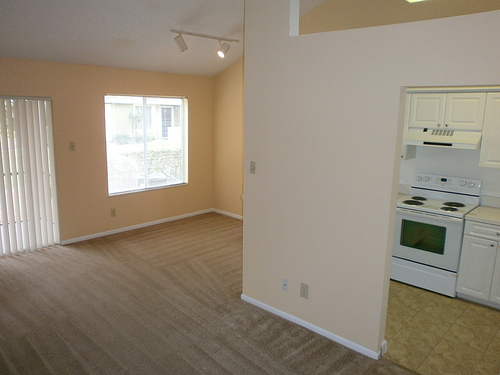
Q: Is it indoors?
A: Yes, it is indoors.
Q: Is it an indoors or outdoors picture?
A: It is indoors.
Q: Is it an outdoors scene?
A: No, it is indoors.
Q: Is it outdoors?
A: No, it is indoors.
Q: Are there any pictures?
A: No, there are no pictures.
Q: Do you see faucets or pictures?
A: No, there are no pictures or faucets.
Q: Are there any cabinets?
A: Yes, there is a cabinet.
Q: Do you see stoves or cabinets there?
A: Yes, there is a cabinet.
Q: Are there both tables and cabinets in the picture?
A: No, there is a cabinet but no tables.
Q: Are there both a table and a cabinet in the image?
A: No, there is a cabinet but no tables.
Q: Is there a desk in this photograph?
A: No, there are no desks.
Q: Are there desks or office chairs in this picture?
A: No, there are no desks or office chairs.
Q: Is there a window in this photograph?
A: Yes, there is a window.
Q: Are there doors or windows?
A: Yes, there is a window.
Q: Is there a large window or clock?
A: Yes, there is a large window.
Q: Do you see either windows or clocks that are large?
A: Yes, the window is large.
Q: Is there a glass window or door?
A: Yes, there is a glass window.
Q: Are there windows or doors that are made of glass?
A: Yes, the window is made of glass.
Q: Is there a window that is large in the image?
A: Yes, there is a large window.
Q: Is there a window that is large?
A: Yes, there is a window that is large.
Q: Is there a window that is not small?
A: Yes, there is a large window.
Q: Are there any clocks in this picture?
A: No, there are no clocks.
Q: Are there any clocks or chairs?
A: No, there are no clocks or chairs.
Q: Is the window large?
A: Yes, the window is large.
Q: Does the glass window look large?
A: Yes, the window is large.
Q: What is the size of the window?
A: The window is large.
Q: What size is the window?
A: The window is large.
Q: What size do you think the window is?
A: The window is large.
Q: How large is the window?
A: The window is large.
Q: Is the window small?
A: No, the window is large.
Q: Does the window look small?
A: No, the window is large.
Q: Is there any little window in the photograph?
A: No, there is a window but it is large.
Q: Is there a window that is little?
A: No, there is a window but it is large.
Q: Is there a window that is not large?
A: No, there is a window but it is large.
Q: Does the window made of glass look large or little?
A: The window is large.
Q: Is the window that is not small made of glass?
A: Yes, the window is made of glass.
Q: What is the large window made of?
A: The window is made of glass.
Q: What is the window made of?
A: The window is made of glass.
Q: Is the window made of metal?
A: No, the window is made of glass.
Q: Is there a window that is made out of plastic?
A: No, there is a window but it is made of glass.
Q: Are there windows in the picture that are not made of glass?
A: No, there is a window but it is made of glass.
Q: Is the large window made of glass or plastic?
A: The window is made of glass.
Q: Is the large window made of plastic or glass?
A: The window is made of glass.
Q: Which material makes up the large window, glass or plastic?
A: The window is made of glass.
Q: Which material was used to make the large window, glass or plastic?
A: The window is made of glass.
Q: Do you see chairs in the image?
A: No, there are no chairs.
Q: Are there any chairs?
A: No, there are no chairs.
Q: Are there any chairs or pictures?
A: No, there are no chairs or pictures.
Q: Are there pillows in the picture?
A: No, there are no pillows.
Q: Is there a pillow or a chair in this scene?
A: No, there are no pillows or chairs.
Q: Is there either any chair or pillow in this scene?
A: No, there are no pillows or chairs.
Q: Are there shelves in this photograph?
A: No, there are no shelves.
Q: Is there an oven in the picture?
A: Yes, there is an oven.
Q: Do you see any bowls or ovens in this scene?
A: Yes, there is an oven.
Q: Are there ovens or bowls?
A: Yes, there is an oven.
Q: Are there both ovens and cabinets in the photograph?
A: Yes, there are both an oven and a cabinet.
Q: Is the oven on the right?
A: Yes, the oven is on the right of the image.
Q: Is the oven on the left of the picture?
A: No, the oven is on the right of the image.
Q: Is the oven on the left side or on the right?
A: The oven is on the right of the image.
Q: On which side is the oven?
A: The oven is on the right of the image.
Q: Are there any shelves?
A: No, there are no shelves.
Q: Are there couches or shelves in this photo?
A: No, there are no shelves or couches.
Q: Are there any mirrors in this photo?
A: No, there are no mirrors.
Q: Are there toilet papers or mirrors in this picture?
A: No, there are no mirrors or toilet papers.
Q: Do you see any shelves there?
A: No, there are no shelves.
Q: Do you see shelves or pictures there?
A: No, there are no shelves or pictures.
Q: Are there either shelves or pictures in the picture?
A: No, there are no shelves or pictures.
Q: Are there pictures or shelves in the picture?
A: No, there are no shelves or pictures.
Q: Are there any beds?
A: No, there are no beds.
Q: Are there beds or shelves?
A: No, there are no beds or shelves.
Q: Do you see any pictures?
A: No, there are no pictures.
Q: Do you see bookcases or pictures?
A: No, there are no pictures or bookcases.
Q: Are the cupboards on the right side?
A: Yes, the cupboards are on the right of the image.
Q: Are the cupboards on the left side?
A: No, the cupboards are on the right of the image.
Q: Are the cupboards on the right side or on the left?
A: The cupboards are on the right of the image.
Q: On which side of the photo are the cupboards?
A: The cupboards are on the right of the image.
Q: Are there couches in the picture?
A: No, there are no couches.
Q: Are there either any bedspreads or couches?
A: No, there are no couches or bedspreads.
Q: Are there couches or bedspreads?
A: No, there are no couches or bedspreads.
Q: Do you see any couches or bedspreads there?
A: No, there are no couches or bedspreads.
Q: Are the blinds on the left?
A: Yes, the blinds are on the left of the image.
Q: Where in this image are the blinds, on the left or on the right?
A: The blinds are on the left of the image.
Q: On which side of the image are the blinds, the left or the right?
A: The blinds are on the left of the image.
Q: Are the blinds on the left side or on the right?
A: The blinds are on the left of the image.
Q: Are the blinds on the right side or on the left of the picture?
A: The blinds are on the left of the image.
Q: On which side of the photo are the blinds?
A: The blinds are on the left of the image.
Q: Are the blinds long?
A: Yes, the blinds are long.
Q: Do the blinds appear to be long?
A: Yes, the blinds are long.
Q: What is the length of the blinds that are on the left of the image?
A: The blinds are long.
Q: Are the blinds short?
A: No, the blinds are long.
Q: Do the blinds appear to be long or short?
A: The blinds are long.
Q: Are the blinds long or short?
A: The blinds are long.